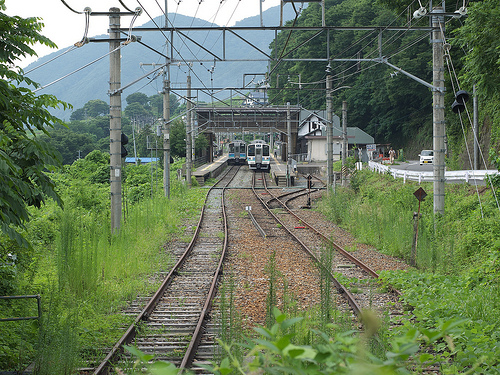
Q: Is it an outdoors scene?
A: Yes, it is outdoors.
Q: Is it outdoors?
A: Yes, it is outdoors.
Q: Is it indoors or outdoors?
A: It is outdoors.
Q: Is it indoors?
A: No, it is outdoors.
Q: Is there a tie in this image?
A: Yes, there is a tie.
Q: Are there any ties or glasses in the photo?
A: Yes, there is a tie.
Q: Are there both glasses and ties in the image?
A: No, there is a tie but no glasses.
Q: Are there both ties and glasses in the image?
A: No, there is a tie but no glasses.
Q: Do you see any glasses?
A: No, there are no glasses.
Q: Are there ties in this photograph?
A: Yes, there is a tie.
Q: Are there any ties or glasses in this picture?
A: Yes, there is a tie.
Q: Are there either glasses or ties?
A: Yes, there is a tie.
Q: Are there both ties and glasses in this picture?
A: No, there is a tie but no glasses.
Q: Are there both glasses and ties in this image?
A: No, there is a tie but no glasses.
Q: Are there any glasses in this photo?
A: No, there are no glasses.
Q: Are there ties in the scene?
A: Yes, there is a tie.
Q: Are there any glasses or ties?
A: Yes, there is a tie.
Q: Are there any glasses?
A: No, there are no glasses.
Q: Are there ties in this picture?
A: Yes, there is a tie.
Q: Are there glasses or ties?
A: Yes, there is a tie.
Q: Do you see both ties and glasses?
A: No, there is a tie but no glasses.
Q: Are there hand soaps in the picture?
A: No, there are no hand soaps.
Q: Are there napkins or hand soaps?
A: No, there are no hand soaps or napkins.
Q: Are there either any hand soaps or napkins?
A: No, there are no hand soaps or napkins.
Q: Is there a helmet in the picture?
A: No, there are no helmets.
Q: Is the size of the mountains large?
A: Yes, the mountains are large.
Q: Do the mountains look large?
A: Yes, the mountains are large.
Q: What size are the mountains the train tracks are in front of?
A: The mountains are large.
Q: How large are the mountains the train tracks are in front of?
A: The mountains are large.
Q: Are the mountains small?
A: No, the mountains are large.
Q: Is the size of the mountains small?
A: No, the mountains are large.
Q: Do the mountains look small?
A: No, the mountains are large.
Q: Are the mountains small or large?
A: The mountains are large.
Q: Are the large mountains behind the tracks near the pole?
A: Yes, the mountains are behind the train tracks.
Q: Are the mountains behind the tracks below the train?
A: Yes, the mountains are behind the train tracks.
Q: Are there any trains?
A: Yes, there is a train.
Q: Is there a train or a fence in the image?
A: Yes, there is a train.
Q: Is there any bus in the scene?
A: No, there are no buses.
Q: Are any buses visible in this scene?
A: No, there are no buses.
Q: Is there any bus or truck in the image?
A: No, there are no buses or trucks.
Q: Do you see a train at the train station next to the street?
A: Yes, there is a train at the train station.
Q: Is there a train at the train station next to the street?
A: Yes, there is a train at the train station.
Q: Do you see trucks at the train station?
A: No, there is a train at the train station.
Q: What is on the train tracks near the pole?
A: The train is on the train tracks.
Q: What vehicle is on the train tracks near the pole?
A: The vehicle is a train.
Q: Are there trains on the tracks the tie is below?
A: Yes, there is a train on the tracks.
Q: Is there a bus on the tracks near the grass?
A: No, there is a train on the tracks.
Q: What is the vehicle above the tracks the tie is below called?
A: The vehicle is a train.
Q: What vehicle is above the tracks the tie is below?
A: The vehicle is a train.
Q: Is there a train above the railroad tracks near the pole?
A: Yes, there is a train above the train tracks.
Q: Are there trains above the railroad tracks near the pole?
A: Yes, there is a train above the train tracks.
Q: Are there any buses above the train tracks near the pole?
A: No, there is a train above the tracks.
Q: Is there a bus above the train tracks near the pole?
A: No, there is a train above the tracks.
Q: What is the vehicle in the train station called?
A: The vehicle is a train.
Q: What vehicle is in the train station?
A: The vehicle is a train.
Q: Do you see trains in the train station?
A: Yes, there is a train in the train station.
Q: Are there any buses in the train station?
A: No, there is a train in the train station.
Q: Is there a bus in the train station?
A: No, there is a train in the train station.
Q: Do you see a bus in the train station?
A: No, there is a train in the train station.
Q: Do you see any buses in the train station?
A: No, there is a train in the train station.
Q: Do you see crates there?
A: No, there are no crates.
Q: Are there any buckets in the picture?
A: No, there are no buckets.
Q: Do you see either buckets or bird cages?
A: No, there are no buckets or bird cages.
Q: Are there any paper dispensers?
A: No, there are no paper dispensers.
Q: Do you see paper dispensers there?
A: No, there are no paper dispensers.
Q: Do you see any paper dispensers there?
A: No, there are no paper dispensers.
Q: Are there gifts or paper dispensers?
A: No, there are no paper dispensers or gifts.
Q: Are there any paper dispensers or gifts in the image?
A: No, there are no paper dispensers or gifts.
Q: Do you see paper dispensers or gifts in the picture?
A: No, there are no paper dispensers or gifts.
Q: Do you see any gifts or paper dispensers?
A: No, there are no paper dispensers or gifts.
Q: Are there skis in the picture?
A: No, there are no skis.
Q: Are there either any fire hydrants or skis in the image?
A: No, there are no skis or fire hydrants.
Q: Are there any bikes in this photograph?
A: No, there are no bikes.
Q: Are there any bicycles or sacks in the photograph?
A: No, there are no bicycles or sacks.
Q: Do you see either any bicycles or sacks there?
A: No, there are no bicycles or sacks.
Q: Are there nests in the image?
A: No, there are no nests.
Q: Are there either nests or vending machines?
A: No, there are no nests or vending machines.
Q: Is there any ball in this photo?
A: No, there are no balls.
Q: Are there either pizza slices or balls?
A: No, there are no balls or pizza slices.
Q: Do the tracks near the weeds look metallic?
A: Yes, the railroad tracks are metallic.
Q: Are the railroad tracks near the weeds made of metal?
A: Yes, the tracks are made of metal.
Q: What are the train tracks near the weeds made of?
A: The tracks are made of metal.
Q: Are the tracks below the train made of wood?
A: No, the railroad tracks are made of metal.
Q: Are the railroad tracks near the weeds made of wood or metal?
A: The train tracks are made of metal.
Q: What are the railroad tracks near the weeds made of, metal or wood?
A: The train tracks are made of metal.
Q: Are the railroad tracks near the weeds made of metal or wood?
A: The train tracks are made of metal.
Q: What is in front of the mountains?
A: The train tracks are in front of the mountains.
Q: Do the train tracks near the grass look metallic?
A: Yes, the train tracks are metallic.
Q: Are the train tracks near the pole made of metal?
A: Yes, the train tracks are made of metal.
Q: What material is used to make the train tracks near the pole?
A: The train tracks are made of metal.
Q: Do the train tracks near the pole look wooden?
A: No, the railroad tracks are metallic.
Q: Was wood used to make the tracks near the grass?
A: No, the tracks are made of metal.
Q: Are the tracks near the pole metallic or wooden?
A: The tracks are metallic.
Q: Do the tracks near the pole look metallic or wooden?
A: The tracks are metallic.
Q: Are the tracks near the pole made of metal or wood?
A: The tracks are made of metal.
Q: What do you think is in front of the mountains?
A: The train tracks are in front of the mountains.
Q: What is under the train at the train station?
A: The train tracks are under the train.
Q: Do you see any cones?
A: No, there are no cones.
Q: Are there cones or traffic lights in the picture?
A: No, there are no cones or traffic lights.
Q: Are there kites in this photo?
A: No, there are no kites.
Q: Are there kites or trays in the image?
A: No, there are no kites or trays.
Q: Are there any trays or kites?
A: No, there are no kites or trays.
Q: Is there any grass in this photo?
A: Yes, there is grass.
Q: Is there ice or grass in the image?
A: Yes, there is grass.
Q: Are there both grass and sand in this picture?
A: No, there is grass but no sand.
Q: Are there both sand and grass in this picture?
A: No, there is grass but no sand.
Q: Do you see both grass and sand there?
A: No, there is grass but no sand.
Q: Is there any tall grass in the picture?
A: Yes, there is tall grass.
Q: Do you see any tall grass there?
A: Yes, there is tall grass.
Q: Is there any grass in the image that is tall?
A: Yes, there is tall grass.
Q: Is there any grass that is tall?
A: Yes, there is grass that is tall.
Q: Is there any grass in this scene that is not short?
A: Yes, there is tall grass.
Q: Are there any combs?
A: No, there are no combs.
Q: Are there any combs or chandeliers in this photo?
A: No, there are no combs or chandeliers.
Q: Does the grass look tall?
A: Yes, the grass is tall.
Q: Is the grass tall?
A: Yes, the grass is tall.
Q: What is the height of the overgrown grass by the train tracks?
A: The grass is tall.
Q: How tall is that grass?
A: The grass is tall.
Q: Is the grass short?
A: No, the grass is tall.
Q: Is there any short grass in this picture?
A: No, there is grass but it is tall.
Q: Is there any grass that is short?
A: No, there is grass but it is tall.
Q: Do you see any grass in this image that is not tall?
A: No, there is grass but it is tall.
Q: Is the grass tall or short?
A: The grass is tall.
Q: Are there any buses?
A: No, there are no buses.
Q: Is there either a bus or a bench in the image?
A: No, there are no buses or benches.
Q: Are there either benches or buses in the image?
A: No, there are no buses or benches.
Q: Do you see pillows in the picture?
A: No, there are no pillows.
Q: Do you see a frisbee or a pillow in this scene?
A: No, there are no pillows or frisbees.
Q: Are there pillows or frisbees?
A: No, there are no pillows or frisbees.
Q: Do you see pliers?
A: No, there are no pliers.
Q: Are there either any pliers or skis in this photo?
A: No, there are no pliers or skis.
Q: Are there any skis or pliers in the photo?
A: No, there are no pliers or skis.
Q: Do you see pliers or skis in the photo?
A: No, there are no pliers or skis.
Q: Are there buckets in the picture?
A: No, there are no buckets.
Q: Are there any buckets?
A: No, there are no buckets.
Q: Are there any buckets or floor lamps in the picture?
A: No, there are no buckets or floor lamps.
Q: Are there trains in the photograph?
A: Yes, there is a train.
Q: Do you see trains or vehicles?
A: Yes, there is a train.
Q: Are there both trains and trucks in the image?
A: No, there is a train but no trucks.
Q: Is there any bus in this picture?
A: No, there are no buses.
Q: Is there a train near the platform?
A: Yes, there is a train near the platform.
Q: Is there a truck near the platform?
A: No, there is a train near the platform.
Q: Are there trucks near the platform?
A: No, there is a train near the platform.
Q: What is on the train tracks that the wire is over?
A: The train is on the tracks.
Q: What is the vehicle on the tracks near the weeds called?
A: The vehicle is a train.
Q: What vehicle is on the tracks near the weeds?
A: The vehicle is a train.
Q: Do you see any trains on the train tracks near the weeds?
A: Yes, there is a train on the train tracks.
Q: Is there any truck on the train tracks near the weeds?
A: No, there is a train on the railroad tracks.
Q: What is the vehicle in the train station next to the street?
A: The vehicle is a train.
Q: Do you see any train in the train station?
A: Yes, there is a train in the train station.